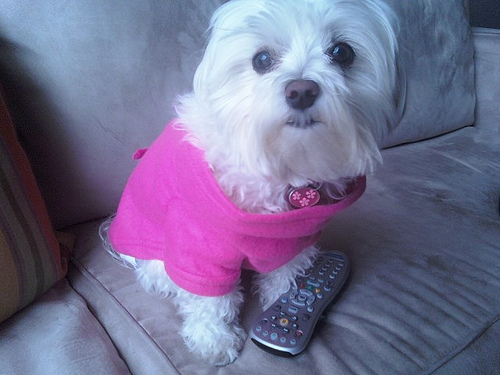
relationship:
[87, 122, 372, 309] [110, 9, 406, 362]
dog clothing on dog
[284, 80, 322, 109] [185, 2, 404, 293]
black nose on dog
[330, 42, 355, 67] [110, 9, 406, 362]
eye on dog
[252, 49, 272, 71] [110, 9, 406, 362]
eye on dog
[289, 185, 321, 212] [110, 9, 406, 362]
collar on dog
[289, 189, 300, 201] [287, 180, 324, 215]
flower on tag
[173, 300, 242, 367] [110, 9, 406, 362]
paw of dog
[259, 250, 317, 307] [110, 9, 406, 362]
paw of dog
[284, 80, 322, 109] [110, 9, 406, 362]
black nose of dog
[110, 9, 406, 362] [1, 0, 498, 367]
dog on couch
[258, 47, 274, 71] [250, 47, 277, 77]
light in eye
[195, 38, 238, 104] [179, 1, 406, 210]
ear on dog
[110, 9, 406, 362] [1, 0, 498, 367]
dog sitting on couch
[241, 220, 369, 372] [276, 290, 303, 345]
remote with buttons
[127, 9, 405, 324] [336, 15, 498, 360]
dog on couch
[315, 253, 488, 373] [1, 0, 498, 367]
wrinkles on couch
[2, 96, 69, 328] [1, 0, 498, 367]
pillow on couch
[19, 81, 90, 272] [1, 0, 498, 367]
shadow of pillow on couch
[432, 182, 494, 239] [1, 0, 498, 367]
stains on couch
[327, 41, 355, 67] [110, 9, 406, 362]
eye of dog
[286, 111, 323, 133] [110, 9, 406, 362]
mouth of dog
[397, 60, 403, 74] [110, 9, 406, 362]
ear of dog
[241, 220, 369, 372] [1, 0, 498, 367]
remote on couch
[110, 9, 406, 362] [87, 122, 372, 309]
dog has a dog clothing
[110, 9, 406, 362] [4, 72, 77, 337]
dog on cushion